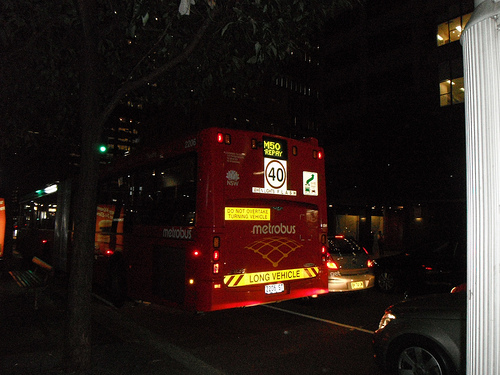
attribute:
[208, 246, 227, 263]
light — rear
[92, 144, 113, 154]
light — green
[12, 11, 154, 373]
tree — tall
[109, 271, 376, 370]
street — dark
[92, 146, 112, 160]
light — green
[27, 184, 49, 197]
light — green